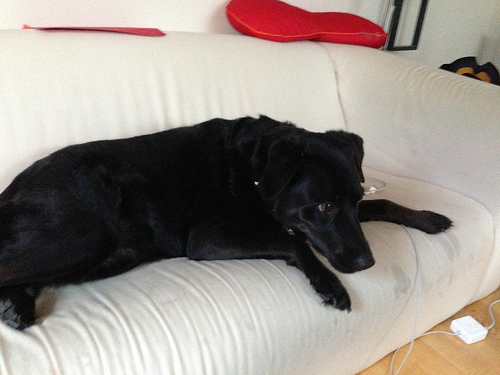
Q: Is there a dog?
A: Yes, there is a dog.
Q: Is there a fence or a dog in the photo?
A: Yes, there is a dog.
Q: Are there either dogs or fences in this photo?
A: Yes, there is a dog.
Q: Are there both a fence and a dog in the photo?
A: No, there is a dog but no fences.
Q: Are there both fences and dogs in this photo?
A: No, there is a dog but no fences.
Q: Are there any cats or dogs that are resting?
A: Yes, the dog is resting.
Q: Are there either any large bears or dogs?
A: Yes, there is a large dog.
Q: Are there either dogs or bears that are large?
A: Yes, the dog is large.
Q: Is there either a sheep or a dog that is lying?
A: Yes, the dog is lying.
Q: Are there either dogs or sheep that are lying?
A: Yes, the dog is lying.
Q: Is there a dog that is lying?
A: Yes, there is a dog that is lying.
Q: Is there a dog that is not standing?
A: Yes, there is a dog that is lying.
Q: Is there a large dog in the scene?
A: Yes, there is a large dog.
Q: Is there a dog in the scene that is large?
A: Yes, there is a dog that is large.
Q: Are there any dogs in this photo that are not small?
A: Yes, there is a large dog.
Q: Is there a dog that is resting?
A: Yes, there is a dog that is resting.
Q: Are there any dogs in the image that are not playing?
A: Yes, there is a dog that is resting.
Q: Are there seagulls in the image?
A: No, there are no seagulls.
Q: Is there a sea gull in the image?
A: No, there are no seagulls.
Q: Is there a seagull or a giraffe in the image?
A: No, there are no seagulls or giraffes.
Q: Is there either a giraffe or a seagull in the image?
A: No, there are no seagulls or giraffes.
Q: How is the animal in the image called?
A: The animal is a dog.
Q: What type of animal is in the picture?
A: The animal is a dog.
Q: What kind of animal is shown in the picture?
A: The animal is a dog.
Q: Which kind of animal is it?
A: The animal is a dog.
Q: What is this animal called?
A: This is a dog.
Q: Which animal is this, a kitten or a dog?
A: This is a dog.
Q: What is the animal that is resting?
A: The animal is a dog.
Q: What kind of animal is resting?
A: The animal is a dog.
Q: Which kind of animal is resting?
A: The animal is a dog.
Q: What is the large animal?
A: The animal is a dog.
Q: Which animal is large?
A: The animal is a dog.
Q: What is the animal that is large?
A: The animal is a dog.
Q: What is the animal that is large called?
A: The animal is a dog.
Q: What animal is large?
A: The animal is a dog.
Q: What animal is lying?
A: The animal is a dog.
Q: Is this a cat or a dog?
A: This is a dog.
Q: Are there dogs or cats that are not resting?
A: No, there is a dog but it is resting.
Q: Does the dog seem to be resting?
A: Yes, the dog is resting.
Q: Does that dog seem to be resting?
A: Yes, the dog is resting.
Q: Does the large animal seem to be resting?
A: Yes, the dog is resting.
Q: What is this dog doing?
A: The dog is resting.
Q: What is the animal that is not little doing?
A: The dog is resting.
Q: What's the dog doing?
A: The dog is resting.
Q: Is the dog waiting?
A: No, the dog is resting.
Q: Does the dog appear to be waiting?
A: No, the dog is resting.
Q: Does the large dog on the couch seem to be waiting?
A: No, the dog is resting.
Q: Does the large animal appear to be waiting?
A: No, the dog is resting.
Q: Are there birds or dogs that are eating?
A: No, there is a dog but it is resting.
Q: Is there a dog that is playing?
A: No, there is a dog but it is resting.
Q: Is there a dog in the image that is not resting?
A: No, there is a dog but it is resting.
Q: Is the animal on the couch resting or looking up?
A: The dog is resting.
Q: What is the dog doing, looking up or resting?
A: The dog is resting.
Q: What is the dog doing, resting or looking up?
A: The dog is resting.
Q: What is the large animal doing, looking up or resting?
A: The dog is resting.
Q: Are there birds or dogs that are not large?
A: No, there is a dog but it is large.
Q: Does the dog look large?
A: Yes, the dog is large.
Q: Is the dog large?
A: Yes, the dog is large.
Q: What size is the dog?
A: The dog is large.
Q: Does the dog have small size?
A: No, the dog is large.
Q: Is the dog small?
A: No, the dog is large.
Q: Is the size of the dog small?
A: No, the dog is large.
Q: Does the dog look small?
A: No, the dog is large.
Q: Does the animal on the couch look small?
A: No, the dog is large.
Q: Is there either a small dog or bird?
A: No, there is a dog but it is large.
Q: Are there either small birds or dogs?
A: No, there is a dog but it is large.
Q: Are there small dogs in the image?
A: No, there is a dog but it is large.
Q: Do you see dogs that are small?
A: No, there is a dog but it is large.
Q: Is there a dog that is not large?
A: No, there is a dog but it is large.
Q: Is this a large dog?
A: Yes, this is a large dog.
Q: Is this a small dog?
A: No, this is a large dog.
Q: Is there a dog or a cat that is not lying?
A: No, there is a dog but it is lying.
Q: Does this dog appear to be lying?
A: Yes, the dog is lying.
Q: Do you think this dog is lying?
A: Yes, the dog is lying.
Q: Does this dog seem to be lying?
A: Yes, the dog is lying.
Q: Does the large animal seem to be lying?
A: Yes, the dog is lying.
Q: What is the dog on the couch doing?
A: The dog is lying.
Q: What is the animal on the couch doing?
A: The dog is lying.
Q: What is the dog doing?
A: The dog is lying.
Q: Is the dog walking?
A: No, the dog is lying.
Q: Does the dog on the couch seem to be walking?
A: No, the dog is lying.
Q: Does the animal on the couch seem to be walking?
A: No, the dog is lying.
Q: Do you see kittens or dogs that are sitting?
A: No, there is a dog but it is lying.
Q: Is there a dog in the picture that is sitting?
A: No, there is a dog but it is lying.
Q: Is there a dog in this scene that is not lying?
A: No, there is a dog but it is lying.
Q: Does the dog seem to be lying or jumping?
A: The dog is lying.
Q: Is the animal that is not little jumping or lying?
A: The dog is lying.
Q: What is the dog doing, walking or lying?
A: The dog is lying.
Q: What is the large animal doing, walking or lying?
A: The dog is lying.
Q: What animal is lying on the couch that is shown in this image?
A: The dog is lying on the couch.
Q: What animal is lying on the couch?
A: The dog is lying on the couch.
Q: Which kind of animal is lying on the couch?
A: The animal is a dog.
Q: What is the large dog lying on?
A: The dog is lying on the couch.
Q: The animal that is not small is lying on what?
A: The dog is lying on the couch.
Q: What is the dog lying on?
A: The dog is lying on the couch.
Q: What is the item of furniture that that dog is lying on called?
A: The piece of furniture is a couch.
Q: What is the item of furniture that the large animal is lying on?
A: The piece of furniture is a couch.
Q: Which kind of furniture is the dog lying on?
A: The dog is lying on the couch.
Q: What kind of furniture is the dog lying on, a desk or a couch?
A: The dog is lying on a couch.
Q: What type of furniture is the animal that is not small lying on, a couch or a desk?
A: The dog is lying on a couch.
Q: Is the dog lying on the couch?
A: Yes, the dog is lying on the couch.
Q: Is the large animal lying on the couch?
A: Yes, the dog is lying on the couch.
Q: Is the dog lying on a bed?
A: No, the dog is lying on the couch.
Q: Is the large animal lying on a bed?
A: No, the dog is lying on the couch.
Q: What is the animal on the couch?
A: The animal is a dog.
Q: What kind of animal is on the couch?
A: The animal is a dog.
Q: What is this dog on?
A: The dog is on the couch.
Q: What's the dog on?
A: The dog is on the couch.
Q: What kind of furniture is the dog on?
A: The dog is on the couch.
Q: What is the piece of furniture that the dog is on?
A: The piece of furniture is a couch.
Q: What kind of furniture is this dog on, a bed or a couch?
A: The dog is on a couch.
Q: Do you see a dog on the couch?
A: Yes, there is a dog on the couch.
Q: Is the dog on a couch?
A: Yes, the dog is on a couch.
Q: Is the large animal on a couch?
A: Yes, the dog is on a couch.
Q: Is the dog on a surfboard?
A: No, the dog is on a couch.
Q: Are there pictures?
A: No, there are no pictures.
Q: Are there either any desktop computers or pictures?
A: No, there are no pictures or desktop computers.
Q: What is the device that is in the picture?
A: The device is a charger.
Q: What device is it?
A: The device is a charger.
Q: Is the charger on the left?
A: No, the charger is on the right of the image.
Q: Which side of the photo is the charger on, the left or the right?
A: The charger is on the right of the image.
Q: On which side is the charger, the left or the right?
A: The charger is on the right of the image.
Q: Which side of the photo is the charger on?
A: The charger is on the right of the image.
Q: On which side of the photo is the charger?
A: The charger is on the right of the image.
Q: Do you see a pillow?
A: Yes, there is a pillow.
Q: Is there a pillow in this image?
A: Yes, there is a pillow.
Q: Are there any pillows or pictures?
A: Yes, there is a pillow.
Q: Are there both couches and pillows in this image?
A: Yes, there are both a pillow and a couch.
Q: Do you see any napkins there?
A: No, there are no napkins.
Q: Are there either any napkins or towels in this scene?
A: No, there are no napkins or towels.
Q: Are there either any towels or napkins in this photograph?
A: No, there are no napkins or towels.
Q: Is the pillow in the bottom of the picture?
A: No, the pillow is in the top of the image.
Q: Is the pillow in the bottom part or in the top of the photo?
A: The pillow is in the top of the image.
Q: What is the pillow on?
A: The pillow is on the couch.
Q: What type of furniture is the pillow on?
A: The pillow is on the couch.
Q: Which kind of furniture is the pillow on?
A: The pillow is on the couch.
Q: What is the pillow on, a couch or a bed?
A: The pillow is on a couch.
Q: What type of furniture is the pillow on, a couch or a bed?
A: The pillow is on a couch.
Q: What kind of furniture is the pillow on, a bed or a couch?
A: The pillow is on a couch.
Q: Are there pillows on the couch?
A: Yes, there is a pillow on the couch.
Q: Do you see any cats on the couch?
A: No, there is a pillow on the couch.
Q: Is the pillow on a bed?
A: No, the pillow is on a couch.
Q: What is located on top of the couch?
A: The pillow is on top of the couch.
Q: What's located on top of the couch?
A: The pillow is on top of the couch.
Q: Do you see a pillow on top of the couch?
A: Yes, there is a pillow on top of the couch.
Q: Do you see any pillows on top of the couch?
A: Yes, there is a pillow on top of the couch.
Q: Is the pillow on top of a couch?
A: Yes, the pillow is on top of a couch.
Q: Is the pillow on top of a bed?
A: No, the pillow is on top of a couch.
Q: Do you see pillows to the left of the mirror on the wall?
A: Yes, there is a pillow to the left of the mirror.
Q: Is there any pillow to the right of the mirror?
A: No, the pillow is to the left of the mirror.